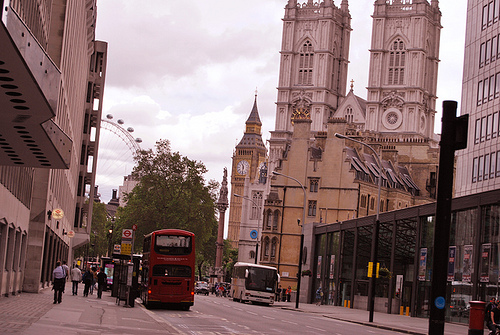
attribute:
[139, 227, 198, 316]
bus — double decker, black, red, white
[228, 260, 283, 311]
bus — white, stopped, big, tour, on the right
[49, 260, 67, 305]
pedestrian — walking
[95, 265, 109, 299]
pedestrian — walking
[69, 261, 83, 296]
pedestrian — walking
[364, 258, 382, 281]
sign — yellow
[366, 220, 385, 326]
pole — black, long, light, street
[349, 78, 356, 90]
steeple — at top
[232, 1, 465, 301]
building — tall, ornate, large, brown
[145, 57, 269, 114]
clouds — puffy, white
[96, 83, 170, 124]
clouds — puffy, white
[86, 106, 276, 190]
clouds — puffy, white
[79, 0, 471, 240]
sky — cloudy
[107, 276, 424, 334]
street — paved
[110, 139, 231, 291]
tree — big, fluff, green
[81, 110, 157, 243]
ferris wheel — large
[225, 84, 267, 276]
clock tower — large, brown, on right, big ben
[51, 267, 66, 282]
shirt — blue, light blue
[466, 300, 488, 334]
can — trash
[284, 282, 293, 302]
person — in red